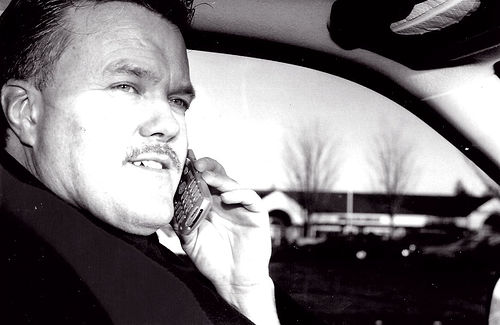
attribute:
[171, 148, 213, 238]
cellphone — small, grey, flip phone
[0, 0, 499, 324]
car — black, white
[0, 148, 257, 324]
jacket — black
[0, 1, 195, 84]
hair — short